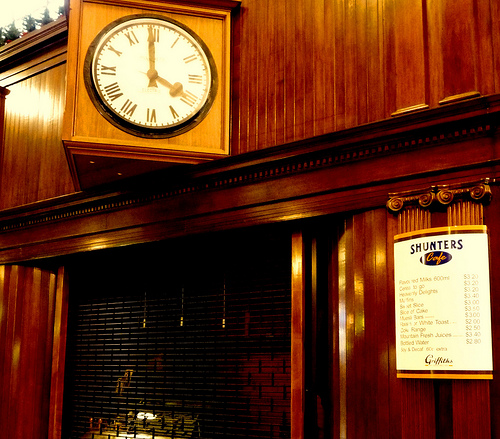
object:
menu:
[392, 225, 493, 380]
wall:
[226, 0, 500, 156]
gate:
[52, 256, 287, 438]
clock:
[81, 13, 218, 140]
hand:
[144, 25, 159, 88]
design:
[267, 135, 320, 180]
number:
[145, 107, 158, 123]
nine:
[99, 62, 121, 76]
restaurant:
[0, 0, 500, 432]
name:
[409, 238, 466, 254]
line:
[392, 224, 487, 243]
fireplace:
[84, 394, 211, 439]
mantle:
[0, 124, 496, 235]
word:
[407, 239, 464, 255]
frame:
[82, 14, 220, 140]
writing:
[397, 273, 484, 355]